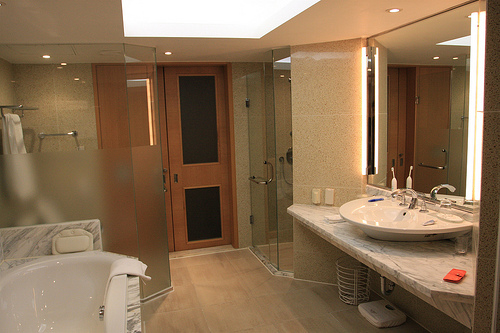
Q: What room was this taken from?
A: Bathroom.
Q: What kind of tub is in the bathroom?
A: Jacuzzi.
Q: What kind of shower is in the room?
A: Walk in shower.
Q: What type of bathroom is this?
A: A modern one.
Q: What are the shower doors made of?
A: Glass.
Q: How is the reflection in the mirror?
A: Of the shower.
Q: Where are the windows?
A: On the wooden door.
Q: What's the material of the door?
A: It is wooden.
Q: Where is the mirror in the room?
A: Above the sink.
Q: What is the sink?
A: An above counter sink.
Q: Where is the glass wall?
A: All around the bathroom.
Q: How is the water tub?
A: It is white.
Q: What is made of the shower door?
A: It is glass.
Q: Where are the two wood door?
A: Across the shower door.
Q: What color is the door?
A: Brown.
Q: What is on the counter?
A: Wallet.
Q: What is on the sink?
A: Toothbrush.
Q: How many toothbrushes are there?
A: One.